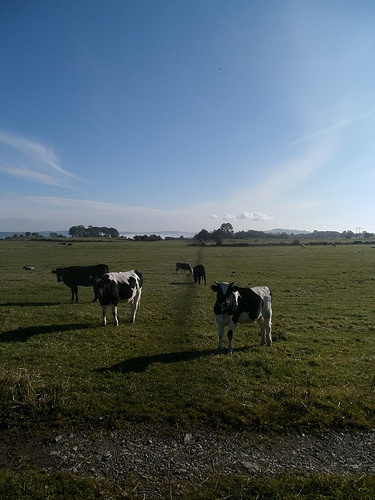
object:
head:
[209, 280, 239, 308]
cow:
[209, 279, 272, 355]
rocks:
[182, 432, 194, 448]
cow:
[51, 264, 109, 306]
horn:
[226, 281, 236, 289]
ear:
[231, 284, 239, 295]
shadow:
[0, 322, 108, 343]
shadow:
[93, 343, 265, 374]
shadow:
[168, 280, 196, 288]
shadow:
[0, 300, 64, 309]